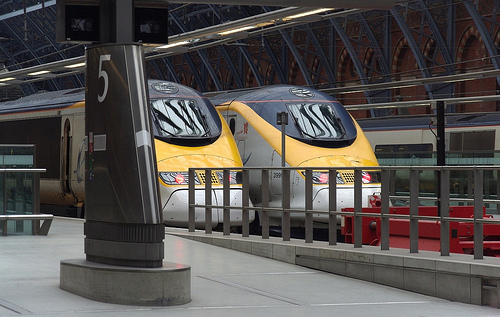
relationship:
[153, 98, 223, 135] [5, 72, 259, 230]
windshield of train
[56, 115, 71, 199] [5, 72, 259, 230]
door on train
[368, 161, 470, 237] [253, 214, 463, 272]
railing near track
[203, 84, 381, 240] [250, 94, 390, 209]
train has end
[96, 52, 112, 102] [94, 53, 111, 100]
sign has number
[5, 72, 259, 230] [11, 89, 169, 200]
train has side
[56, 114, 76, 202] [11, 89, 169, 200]
entrance on side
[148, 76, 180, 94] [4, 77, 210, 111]
emblem on top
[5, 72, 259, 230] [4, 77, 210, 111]
train has top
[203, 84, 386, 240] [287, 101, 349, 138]
train has windshield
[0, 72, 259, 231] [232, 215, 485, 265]
train on tracks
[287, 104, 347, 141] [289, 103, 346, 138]
window has reflection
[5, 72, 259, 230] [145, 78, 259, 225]
train has front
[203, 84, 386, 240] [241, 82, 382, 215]
train has front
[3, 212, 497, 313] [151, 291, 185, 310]
concrete has marks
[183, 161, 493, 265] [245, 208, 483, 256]
railing along tracks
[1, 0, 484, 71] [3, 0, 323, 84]
ceiling has lights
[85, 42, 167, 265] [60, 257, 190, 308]
pole has concrete base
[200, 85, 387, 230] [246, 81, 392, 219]
rail has face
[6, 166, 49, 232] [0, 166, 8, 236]
glass has pole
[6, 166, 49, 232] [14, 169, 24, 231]
glass has pole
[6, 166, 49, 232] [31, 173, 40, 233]
glass has pole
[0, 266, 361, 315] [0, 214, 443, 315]
slabs for walking area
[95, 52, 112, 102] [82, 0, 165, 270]
number on post